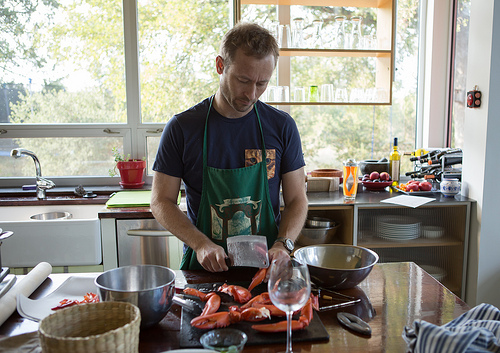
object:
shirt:
[151, 94, 305, 255]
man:
[149, 22, 308, 283]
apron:
[180, 93, 280, 270]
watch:
[273, 237, 294, 255]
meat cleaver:
[224, 234, 270, 268]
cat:
[245, 149, 276, 180]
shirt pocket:
[246, 150, 274, 176]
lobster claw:
[183, 287, 221, 316]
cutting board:
[179, 281, 330, 347]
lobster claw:
[189, 305, 270, 329]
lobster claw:
[251, 296, 312, 331]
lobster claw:
[247, 268, 267, 292]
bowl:
[293, 244, 380, 290]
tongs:
[171, 296, 204, 317]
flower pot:
[116, 159, 145, 189]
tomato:
[418, 182, 432, 191]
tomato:
[406, 182, 418, 191]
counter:
[97, 179, 476, 219]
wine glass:
[267, 257, 311, 352]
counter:
[0, 262, 500, 353]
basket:
[37, 301, 141, 352]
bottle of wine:
[389, 137, 401, 181]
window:
[0, 0, 427, 187]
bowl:
[29, 212, 72, 220]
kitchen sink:
[0, 205, 102, 268]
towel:
[400, 302, 500, 352]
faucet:
[9, 148, 55, 199]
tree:
[0, 0, 470, 177]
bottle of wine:
[427, 157, 462, 165]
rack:
[393, 147, 471, 203]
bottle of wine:
[424, 171, 461, 182]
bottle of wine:
[410, 148, 462, 166]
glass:
[349, 16, 363, 50]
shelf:
[233, 0, 394, 53]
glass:
[336, 16, 344, 49]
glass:
[293, 17, 304, 48]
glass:
[277, 24, 292, 49]